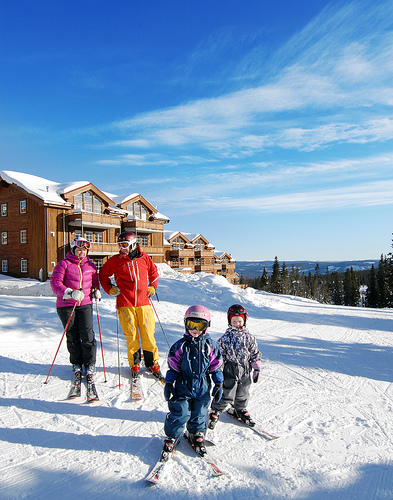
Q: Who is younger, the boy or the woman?
A: The boy is younger than the woman.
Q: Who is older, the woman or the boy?
A: The woman is older than the boy.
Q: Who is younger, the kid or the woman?
A: The kid is younger than the woman.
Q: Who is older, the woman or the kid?
A: The woman is older than the kid.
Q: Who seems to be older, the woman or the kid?
A: The woman is older than the kid.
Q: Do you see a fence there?
A: No, there are no fences.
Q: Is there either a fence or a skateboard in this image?
A: No, there are no fences or skateboards.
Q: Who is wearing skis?
A: The boy is wearing skis.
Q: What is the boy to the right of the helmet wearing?
A: The boy is wearing skis.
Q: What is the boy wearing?
A: The boy is wearing skis.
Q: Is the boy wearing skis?
A: Yes, the boy is wearing skis.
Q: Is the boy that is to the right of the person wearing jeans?
A: No, the boy is wearing skis.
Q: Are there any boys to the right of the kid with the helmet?
A: Yes, there is a boy to the right of the child.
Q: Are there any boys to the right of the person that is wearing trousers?
A: Yes, there is a boy to the right of the child.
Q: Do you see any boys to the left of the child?
A: No, the boy is to the right of the child.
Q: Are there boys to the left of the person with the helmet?
A: No, the boy is to the right of the child.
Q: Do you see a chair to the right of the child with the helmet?
A: No, there is a boy to the right of the kid.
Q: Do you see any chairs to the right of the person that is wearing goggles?
A: No, there is a boy to the right of the kid.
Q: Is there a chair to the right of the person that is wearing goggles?
A: No, there is a boy to the right of the kid.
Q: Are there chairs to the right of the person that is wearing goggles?
A: No, there is a boy to the right of the kid.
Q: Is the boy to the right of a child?
A: Yes, the boy is to the right of a child.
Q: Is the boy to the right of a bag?
A: No, the boy is to the right of a child.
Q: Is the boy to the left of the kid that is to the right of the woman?
A: No, the boy is to the right of the kid.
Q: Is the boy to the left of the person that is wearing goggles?
A: No, the boy is to the right of the kid.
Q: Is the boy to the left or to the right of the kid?
A: The boy is to the right of the kid.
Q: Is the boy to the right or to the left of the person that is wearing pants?
A: The boy is to the right of the kid.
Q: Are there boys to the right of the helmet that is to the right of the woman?
A: Yes, there is a boy to the right of the helmet.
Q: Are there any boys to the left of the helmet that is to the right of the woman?
A: No, the boy is to the right of the helmet.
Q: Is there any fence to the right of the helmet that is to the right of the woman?
A: No, there is a boy to the right of the helmet.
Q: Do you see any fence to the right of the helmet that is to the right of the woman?
A: No, there is a boy to the right of the helmet.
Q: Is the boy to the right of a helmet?
A: Yes, the boy is to the right of a helmet.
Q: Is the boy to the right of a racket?
A: No, the boy is to the right of a helmet.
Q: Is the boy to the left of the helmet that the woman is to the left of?
A: No, the boy is to the right of the helmet.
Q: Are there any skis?
A: Yes, there are skis.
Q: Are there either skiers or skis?
A: Yes, there are skis.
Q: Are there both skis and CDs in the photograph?
A: No, there are skis but no cds.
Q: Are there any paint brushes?
A: No, there are no paint brushes.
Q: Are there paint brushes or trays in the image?
A: No, there are no paint brushes or trays.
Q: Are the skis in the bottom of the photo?
A: Yes, the skis are in the bottom of the image.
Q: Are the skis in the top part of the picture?
A: No, the skis are in the bottom of the image.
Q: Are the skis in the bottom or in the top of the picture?
A: The skis are in the bottom of the image.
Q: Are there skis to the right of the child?
A: Yes, there are skis to the right of the child.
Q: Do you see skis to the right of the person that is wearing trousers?
A: Yes, there are skis to the right of the child.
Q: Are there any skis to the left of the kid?
A: No, the skis are to the right of the kid.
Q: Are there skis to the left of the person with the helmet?
A: No, the skis are to the right of the kid.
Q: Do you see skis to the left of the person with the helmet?
A: No, the skis are to the right of the kid.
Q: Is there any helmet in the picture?
A: Yes, there is a helmet.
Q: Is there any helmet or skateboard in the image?
A: Yes, there is a helmet.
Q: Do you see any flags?
A: No, there are no flags.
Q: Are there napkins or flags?
A: No, there are no flags or napkins.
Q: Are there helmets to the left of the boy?
A: Yes, there is a helmet to the left of the boy.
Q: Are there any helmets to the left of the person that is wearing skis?
A: Yes, there is a helmet to the left of the boy.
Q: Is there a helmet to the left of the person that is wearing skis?
A: Yes, there is a helmet to the left of the boy.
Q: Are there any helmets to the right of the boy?
A: No, the helmet is to the left of the boy.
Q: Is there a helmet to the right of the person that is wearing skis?
A: No, the helmet is to the left of the boy.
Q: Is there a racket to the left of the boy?
A: No, there is a helmet to the left of the boy.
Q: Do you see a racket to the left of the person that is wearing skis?
A: No, there is a helmet to the left of the boy.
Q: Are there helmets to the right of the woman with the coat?
A: Yes, there is a helmet to the right of the woman.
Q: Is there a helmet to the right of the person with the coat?
A: Yes, there is a helmet to the right of the woman.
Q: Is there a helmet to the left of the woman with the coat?
A: No, the helmet is to the right of the woman.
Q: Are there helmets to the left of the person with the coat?
A: No, the helmet is to the right of the woman.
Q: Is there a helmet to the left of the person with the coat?
A: No, the helmet is to the right of the woman.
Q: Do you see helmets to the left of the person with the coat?
A: No, the helmet is to the right of the woman.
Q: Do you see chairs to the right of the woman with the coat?
A: No, there is a helmet to the right of the woman.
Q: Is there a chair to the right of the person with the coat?
A: No, there is a helmet to the right of the woman.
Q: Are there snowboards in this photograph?
A: No, there are no snowboards.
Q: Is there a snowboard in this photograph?
A: No, there are no snowboards.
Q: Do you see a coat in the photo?
A: Yes, there is a coat.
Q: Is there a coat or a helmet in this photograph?
A: Yes, there is a coat.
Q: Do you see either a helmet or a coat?
A: Yes, there is a coat.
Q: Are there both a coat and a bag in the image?
A: No, there is a coat but no bags.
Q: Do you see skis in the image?
A: Yes, there are skis.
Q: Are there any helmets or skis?
A: Yes, there are skis.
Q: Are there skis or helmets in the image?
A: Yes, there are skis.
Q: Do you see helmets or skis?
A: Yes, there are skis.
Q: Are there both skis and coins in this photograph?
A: No, there are skis but no coins.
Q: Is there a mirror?
A: No, there are no mirrors.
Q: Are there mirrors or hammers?
A: No, there are no mirrors or hammers.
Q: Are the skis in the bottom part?
A: Yes, the skis are in the bottom of the image.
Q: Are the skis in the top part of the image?
A: No, the skis are in the bottom of the image.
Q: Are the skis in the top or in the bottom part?
A: The skis are in the bottom of the image.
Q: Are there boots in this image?
A: Yes, there are boots.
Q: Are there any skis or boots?
A: Yes, there are boots.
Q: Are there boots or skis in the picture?
A: Yes, there are boots.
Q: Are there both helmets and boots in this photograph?
A: Yes, there are both boots and a helmet.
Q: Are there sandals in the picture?
A: No, there are no sandals.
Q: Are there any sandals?
A: No, there are no sandals.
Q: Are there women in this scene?
A: Yes, there is a woman.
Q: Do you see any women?
A: Yes, there is a woman.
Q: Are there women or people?
A: Yes, there is a woman.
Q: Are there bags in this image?
A: No, there are no bags.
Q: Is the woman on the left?
A: Yes, the woman is on the left of the image.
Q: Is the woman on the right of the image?
A: No, the woman is on the left of the image.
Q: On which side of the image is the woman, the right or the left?
A: The woman is on the left of the image.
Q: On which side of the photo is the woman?
A: The woman is on the left of the image.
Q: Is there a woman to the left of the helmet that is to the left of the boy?
A: Yes, there is a woman to the left of the helmet.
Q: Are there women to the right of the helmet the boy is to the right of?
A: No, the woman is to the left of the helmet.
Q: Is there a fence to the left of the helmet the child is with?
A: No, there is a woman to the left of the helmet.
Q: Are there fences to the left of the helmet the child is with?
A: No, there is a woman to the left of the helmet.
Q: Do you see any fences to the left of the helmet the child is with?
A: No, there is a woman to the left of the helmet.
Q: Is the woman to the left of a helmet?
A: Yes, the woman is to the left of a helmet.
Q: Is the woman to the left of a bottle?
A: No, the woman is to the left of a helmet.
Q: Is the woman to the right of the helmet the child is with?
A: No, the woman is to the left of the helmet.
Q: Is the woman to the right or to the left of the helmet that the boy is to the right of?
A: The woman is to the left of the helmet.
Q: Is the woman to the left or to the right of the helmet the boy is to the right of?
A: The woman is to the left of the helmet.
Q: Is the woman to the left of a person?
A: Yes, the woman is to the left of a person.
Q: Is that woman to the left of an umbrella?
A: No, the woman is to the left of a person.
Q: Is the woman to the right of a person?
A: No, the woman is to the left of a person.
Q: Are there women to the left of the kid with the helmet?
A: Yes, there is a woman to the left of the child.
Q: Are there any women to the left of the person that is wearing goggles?
A: Yes, there is a woman to the left of the child.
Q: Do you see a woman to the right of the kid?
A: No, the woman is to the left of the kid.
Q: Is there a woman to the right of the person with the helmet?
A: No, the woman is to the left of the kid.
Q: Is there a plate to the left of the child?
A: No, there is a woman to the left of the child.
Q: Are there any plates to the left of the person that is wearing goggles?
A: No, there is a woman to the left of the child.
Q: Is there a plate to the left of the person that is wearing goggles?
A: No, there is a woman to the left of the child.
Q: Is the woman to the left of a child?
A: Yes, the woman is to the left of a child.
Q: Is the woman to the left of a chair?
A: No, the woman is to the left of a child.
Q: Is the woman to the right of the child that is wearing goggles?
A: No, the woman is to the left of the child.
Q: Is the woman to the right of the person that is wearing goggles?
A: No, the woman is to the left of the child.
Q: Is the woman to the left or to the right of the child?
A: The woman is to the left of the child.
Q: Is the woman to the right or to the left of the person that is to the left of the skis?
A: The woman is to the left of the child.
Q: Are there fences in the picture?
A: No, there are no fences.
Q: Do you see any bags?
A: No, there are no bags.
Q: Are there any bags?
A: No, there are no bags.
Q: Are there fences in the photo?
A: No, there are no fences.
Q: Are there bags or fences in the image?
A: No, there are no fences or bags.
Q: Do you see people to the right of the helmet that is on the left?
A: Yes, there is a person to the right of the helmet.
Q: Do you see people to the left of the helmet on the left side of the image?
A: No, the person is to the right of the helmet.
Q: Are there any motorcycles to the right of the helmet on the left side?
A: No, there is a person to the right of the helmet.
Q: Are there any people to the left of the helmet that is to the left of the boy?
A: Yes, there is a person to the left of the helmet.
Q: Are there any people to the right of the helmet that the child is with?
A: No, the person is to the left of the helmet.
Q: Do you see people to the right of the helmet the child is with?
A: No, the person is to the left of the helmet.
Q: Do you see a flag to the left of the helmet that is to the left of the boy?
A: No, there is a person to the left of the helmet.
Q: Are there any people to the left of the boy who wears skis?
A: Yes, there is a person to the left of the boy.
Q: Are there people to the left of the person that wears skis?
A: Yes, there is a person to the left of the boy.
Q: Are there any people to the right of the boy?
A: No, the person is to the left of the boy.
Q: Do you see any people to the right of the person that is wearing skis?
A: No, the person is to the left of the boy.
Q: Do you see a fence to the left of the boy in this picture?
A: No, there is a person to the left of the boy.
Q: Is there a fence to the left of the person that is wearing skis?
A: No, there is a person to the left of the boy.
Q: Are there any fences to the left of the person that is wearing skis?
A: No, there is a person to the left of the boy.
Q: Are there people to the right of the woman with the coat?
A: Yes, there is a person to the right of the woman.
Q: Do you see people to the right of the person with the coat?
A: Yes, there is a person to the right of the woman.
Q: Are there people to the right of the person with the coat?
A: Yes, there is a person to the right of the woman.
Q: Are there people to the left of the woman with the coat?
A: No, the person is to the right of the woman.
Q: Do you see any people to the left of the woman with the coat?
A: No, the person is to the right of the woman.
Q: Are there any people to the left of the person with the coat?
A: No, the person is to the right of the woman.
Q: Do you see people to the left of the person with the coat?
A: No, the person is to the right of the woman.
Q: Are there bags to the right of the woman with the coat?
A: No, there is a person to the right of the woman.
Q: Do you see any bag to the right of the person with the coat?
A: No, there is a person to the right of the woman.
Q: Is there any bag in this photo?
A: No, there are no bags.